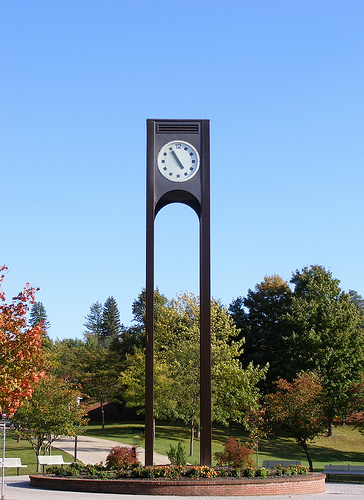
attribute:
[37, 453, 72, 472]
bench — white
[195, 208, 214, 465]
pole — tall, brown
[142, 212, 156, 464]
pole — brown, tall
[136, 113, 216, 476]
clock tower — metallic, dark brown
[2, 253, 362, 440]
trees — green, red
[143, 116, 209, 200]
clock tower — black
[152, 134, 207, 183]
clock — white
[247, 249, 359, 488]
tree — tall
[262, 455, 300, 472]
bench — white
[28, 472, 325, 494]
planter — brick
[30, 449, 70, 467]
bench — empty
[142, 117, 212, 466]
clock — large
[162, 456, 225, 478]
flowers — orange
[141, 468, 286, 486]
wall — brick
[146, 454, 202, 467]
flowers — salmon colored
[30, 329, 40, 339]
leaves — red, yellow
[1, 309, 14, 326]
leaves — yellow, red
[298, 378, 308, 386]
leaves — red, yellow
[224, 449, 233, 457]
leaves — yellow, red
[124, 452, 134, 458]
leaves — red, yellow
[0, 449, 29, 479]
bench — white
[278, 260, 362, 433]
tree — green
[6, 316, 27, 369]
leaves — red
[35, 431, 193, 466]
pathway — paved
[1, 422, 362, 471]
hill — green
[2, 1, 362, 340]
sky — beautiful, blue, clear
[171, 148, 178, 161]
hand — black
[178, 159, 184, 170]
hand — black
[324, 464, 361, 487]
bench — empty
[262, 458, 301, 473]
bench — empty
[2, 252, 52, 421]
leaves — red